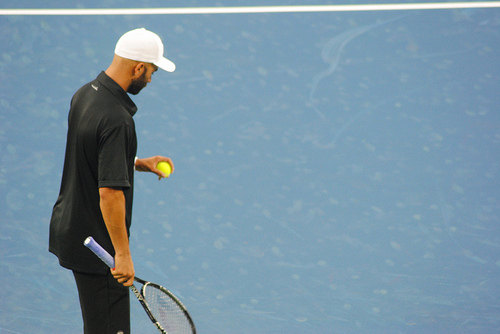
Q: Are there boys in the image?
A: No, there are no boys.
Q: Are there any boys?
A: No, there are no boys.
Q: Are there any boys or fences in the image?
A: No, there are no boys or fences.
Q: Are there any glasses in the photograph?
A: No, there are no glasses.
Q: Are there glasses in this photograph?
A: No, there are no glasses.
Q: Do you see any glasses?
A: No, there are no glasses.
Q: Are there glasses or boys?
A: No, there are no glasses or boys.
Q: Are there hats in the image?
A: Yes, there is a hat.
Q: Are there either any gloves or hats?
A: Yes, there is a hat.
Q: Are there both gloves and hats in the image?
A: No, there is a hat but no gloves.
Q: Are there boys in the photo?
A: No, there are no boys.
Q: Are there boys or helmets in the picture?
A: No, there are no boys or helmets.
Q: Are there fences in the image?
A: No, there are no fences.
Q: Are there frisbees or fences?
A: No, there are no fences or frisbees.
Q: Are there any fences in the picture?
A: No, there are no fences.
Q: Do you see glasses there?
A: No, there are no glasses.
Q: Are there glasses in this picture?
A: No, there are no glasses.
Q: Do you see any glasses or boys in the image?
A: No, there are no glasses or boys.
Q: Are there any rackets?
A: Yes, there is a racket.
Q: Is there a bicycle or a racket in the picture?
A: Yes, there is a racket.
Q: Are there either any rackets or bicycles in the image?
A: Yes, there is a racket.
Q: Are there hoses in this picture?
A: No, there are no hoses.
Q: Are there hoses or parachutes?
A: No, there are no hoses or parachutes.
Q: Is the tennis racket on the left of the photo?
A: Yes, the tennis racket is on the left of the image.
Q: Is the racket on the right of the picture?
A: No, the racket is on the left of the image.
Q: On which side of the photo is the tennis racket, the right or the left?
A: The tennis racket is on the left of the image.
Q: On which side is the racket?
A: The racket is on the left of the image.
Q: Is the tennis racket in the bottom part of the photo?
A: Yes, the tennis racket is in the bottom of the image.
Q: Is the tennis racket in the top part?
A: No, the tennis racket is in the bottom of the image.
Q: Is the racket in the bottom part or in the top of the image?
A: The racket is in the bottom of the image.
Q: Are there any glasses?
A: No, there are no glasses.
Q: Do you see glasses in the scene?
A: No, there are no glasses.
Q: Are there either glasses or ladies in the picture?
A: No, there are no glasses or ladies.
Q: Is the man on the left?
A: Yes, the man is on the left of the image.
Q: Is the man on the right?
A: No, the man is on the left of the image.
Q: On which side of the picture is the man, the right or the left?
A: The man is on the left of the image.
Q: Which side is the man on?
A: The man is on the left of the image.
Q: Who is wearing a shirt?
A: The man is wearing a shirt.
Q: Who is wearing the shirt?
A: The man is wearing a shirt.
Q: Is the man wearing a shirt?
A: Yes, the man is wearing a shirt.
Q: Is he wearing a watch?
A: No, the man is wearing a shirt.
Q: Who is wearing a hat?
A: The man is wearing a hat.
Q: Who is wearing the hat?
A: The man is wearing a hat.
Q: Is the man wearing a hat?
A: Yes, the man is wearing a hat.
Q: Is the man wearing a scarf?
A: No, the man is wearing a hat.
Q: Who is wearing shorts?
A: The man is wearing shorts.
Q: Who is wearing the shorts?
A: The man is wearing shorts.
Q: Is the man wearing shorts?
A: Yes, the man is wearing shorts.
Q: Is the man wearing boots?
A: No, the man is wearing shorts.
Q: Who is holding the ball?
A: The man is holding the ball.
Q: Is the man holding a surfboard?
A: No, the man is holding the ball.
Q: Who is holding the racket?
A: The man is holding the racket.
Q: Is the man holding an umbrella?
A: No, the man is holding the tennis racket.